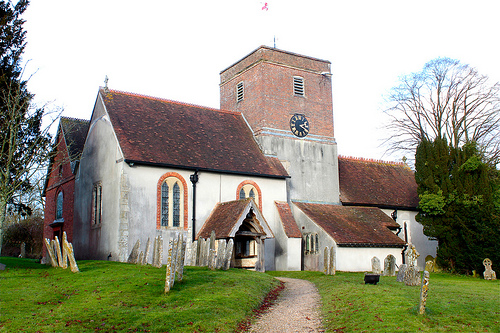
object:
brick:
[258, 194, 263, 196]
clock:
[289, 112, 310, 139]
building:
[71, 72, 306, 271]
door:
[233, 235, 258, 270]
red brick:
[101, 86, 291, 177]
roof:
[98, 87, 290, 178]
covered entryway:
[194, 198, 279, 274]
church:
[35, 33, 444, 272]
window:
[158, 178, 171, 227]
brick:
[182, 182, 187, 186]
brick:
[183, 197, 188, 200]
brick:
[183, 219, 188, 223]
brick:
[156, 220, 161, 223]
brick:
[157, 192, 162, 195]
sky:
[415, 3, 491, 51]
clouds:
[47, 60, 93, 87]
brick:
[263, 67, 280, 78]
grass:
[0, 255, 281, 331]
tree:
[415, 132, 499, 282]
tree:
[0, 0, 55, 209]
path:
[237, 273, 326, 331]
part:
[98, 6, 157, 43]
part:
[271, 310, 300, 328]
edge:
[310, 308, 327, 328]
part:
[288, 125, 311, 138]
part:
[95, 273, 146, 306]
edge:
[114, 163, 123, 260]